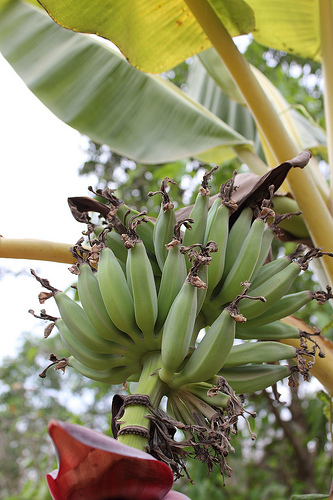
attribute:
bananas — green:
[28, 165, 331, 419]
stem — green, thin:
[114, 354, 169, 447]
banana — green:
[130, 223, 162, 349]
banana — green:
[159, 232, 201, 372]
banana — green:
[208, 193, 230, 296]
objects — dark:
[199, 168, 229, 197]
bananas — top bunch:
[210, 217, 258, 280]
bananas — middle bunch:
[40, 240, 214, 376]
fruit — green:
[44, 175, 330, 421]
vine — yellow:
[269, 308, 330, 375]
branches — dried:
[120, 382, 252, 477]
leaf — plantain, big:
[33, 0, 258, 76]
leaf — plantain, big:
[221, 0, 321, 60]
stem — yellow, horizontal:
[0, 239, 88, 259]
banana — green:
[95, 244, 139, 341]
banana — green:
[127, 241, 156, 333]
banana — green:
[75, 262, 123, 345]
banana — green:
[53, 291, 117, 353]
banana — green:
[53, 319, 120, 371]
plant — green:
[74, 155, 289, 398]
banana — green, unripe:
[161, 255, 204, 378]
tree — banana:
[0, 1, 330, 497]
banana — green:
[231, 218, 261, 297]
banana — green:
[126, 247, 162, 321]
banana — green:
[238, 271, 302, 317]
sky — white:
[11, 132, 53, 210]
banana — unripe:
[118, 229, 193, 325]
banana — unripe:
[89, 253, 237, 333]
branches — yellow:
[192, 29, 331, 183]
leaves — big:
[52, 7, 277, 167]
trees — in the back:
[2, 325, 274, 460]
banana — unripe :
[11, 174, 235, 410]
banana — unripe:
[52, 180, 329, 433]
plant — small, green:
[25, 169, 322, 488]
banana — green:
[215, 364, 294, 393]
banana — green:
[156, 237, 185, 327]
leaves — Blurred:
[22, 331, 42, 366]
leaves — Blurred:
[37, 394, 70, 415]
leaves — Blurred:
[22, 412, 42, 441]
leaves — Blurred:
[8, 389, 27, 410]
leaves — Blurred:
[41, 453, 57, 467]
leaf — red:
[42, 417, 174, 498]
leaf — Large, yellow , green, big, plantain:
[1, 1, 246, 163]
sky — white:
[11, 123, 90, 352]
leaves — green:
[71, 56, 165, 114]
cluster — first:
[30, 241, 315, 403]